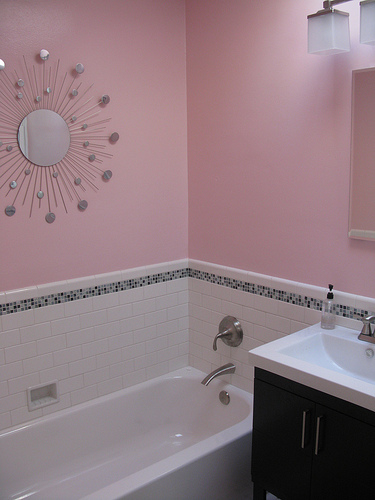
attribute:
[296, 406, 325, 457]
handles — metal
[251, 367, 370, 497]
cabinet — black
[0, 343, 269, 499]
bathtub — white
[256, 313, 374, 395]
sink — white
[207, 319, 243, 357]
handle — silver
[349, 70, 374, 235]
mirror — designed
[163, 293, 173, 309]
tile — white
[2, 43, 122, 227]
design — accent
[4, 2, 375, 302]
wall — pink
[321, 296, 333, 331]
bottle — plastic